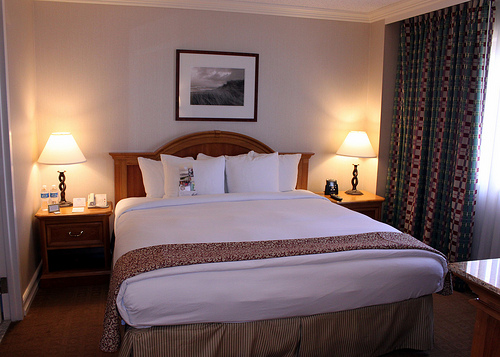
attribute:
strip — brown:
[114, 227, 446, 311]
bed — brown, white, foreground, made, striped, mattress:
[102, 127, 454, 357]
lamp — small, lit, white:
[37, 129, 87, 208]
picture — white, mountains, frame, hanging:
[174, 47, 260, 122]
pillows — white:
[135, 148, 302, 199]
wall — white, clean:
[3, 1, 371, 297]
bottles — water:
[36, 182, 62, 211]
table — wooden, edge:
[328, 192, 386, 224]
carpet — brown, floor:
[3, 279, 475, 354]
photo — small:
[175, 48, 261, 123]